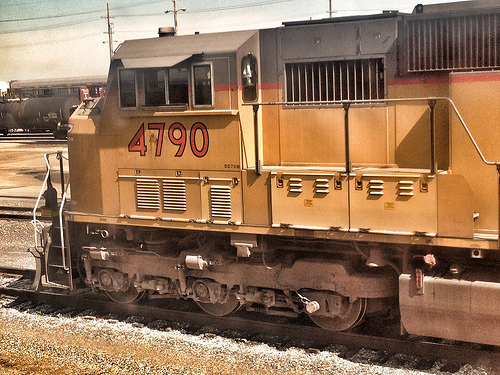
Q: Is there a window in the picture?
A: Yes, there is a window.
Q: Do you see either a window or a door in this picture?
A: Yes, there is a window.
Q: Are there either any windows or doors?
A: Yes, there is a window.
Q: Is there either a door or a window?
A: Yes, there is a window.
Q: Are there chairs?
A: No, there are no chairs.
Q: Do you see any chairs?
A: No, there are no chairs.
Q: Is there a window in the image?
A: Yes, there is a window.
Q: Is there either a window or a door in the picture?
A: Yes, there is a window.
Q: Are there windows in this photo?
A: Yes, there is a window.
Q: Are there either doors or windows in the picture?
A: Yes, there is a window.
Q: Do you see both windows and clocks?
A: No, there is a window but no clocks.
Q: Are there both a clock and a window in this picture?
A: No, there is a window but no clocks.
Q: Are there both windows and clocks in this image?
A: No, there is a window but no clocks.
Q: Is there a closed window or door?
A: Yes, there is a closed window.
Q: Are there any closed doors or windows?
A: Yes, there is a closed window.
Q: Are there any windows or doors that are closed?
A: Yes, the window is closed.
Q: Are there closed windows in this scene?
A: Yes, there is a closed window.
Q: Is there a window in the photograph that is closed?
A: Yes, there is a window that is closed.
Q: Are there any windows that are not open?
A: Yes, there is an closed window.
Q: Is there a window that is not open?
A: Yes, there is an closed window.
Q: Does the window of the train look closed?
A: Yes, the window is closed.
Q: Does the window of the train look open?
A: No, the window is closed.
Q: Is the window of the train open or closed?
A: The window is closed.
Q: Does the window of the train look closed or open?
A: The window is closed.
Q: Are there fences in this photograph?
A: No, there are no fences.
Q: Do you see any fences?
A: No, there are no fences.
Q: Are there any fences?
A: No, there are no fences.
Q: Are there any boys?
A: No, there are no boys.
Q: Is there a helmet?
A: No, there are no helmets.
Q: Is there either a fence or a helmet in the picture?
A: No, there are no helmets or fences.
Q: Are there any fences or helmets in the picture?
A: No, there are no helmets or fences.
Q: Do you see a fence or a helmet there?
A: No, there are no helmets or fences.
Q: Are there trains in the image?
A: Yes, there is a train.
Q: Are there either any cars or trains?
A: Yes, there is a train.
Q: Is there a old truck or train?
A: Yes, there is an old train.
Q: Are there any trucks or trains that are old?
A: Yes, the train is old.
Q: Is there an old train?
A: Yes, there is an old train.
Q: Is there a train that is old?
A: Yes, there is a train that is old.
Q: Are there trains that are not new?
A: Yes, there is a old train.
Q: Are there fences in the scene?
A: No, there are no fences.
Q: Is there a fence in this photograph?
A: No, there are no fences.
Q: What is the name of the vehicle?
A: The vehicle is a train.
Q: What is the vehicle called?
A: The vehicle is a train.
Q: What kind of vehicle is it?
A: The vehicle is a train.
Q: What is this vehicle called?
A: This is a train.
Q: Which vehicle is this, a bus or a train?
A: This is a train.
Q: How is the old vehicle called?
A: The vehicle is a train.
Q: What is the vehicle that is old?
A: The vehicle is a train.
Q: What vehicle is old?
A: The vehicle is a train.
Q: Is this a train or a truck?
A: This is a train.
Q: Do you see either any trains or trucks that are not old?
A: No, there is a train but it is old.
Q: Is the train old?
A: Yes, the train is old.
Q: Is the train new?
A: No, the train is old.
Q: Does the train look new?
A: No, the train is old.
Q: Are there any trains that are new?
A: No, there is a train but it is old.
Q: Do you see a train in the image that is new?
A: No, there is a train but it is old.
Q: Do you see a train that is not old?
A: No, there is a train but it is old.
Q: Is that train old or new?
A: The train is old.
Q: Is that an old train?
A: Yes, that is an old train.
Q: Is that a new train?
A: No, that is an old train.